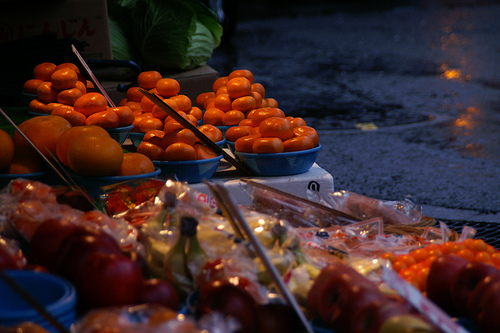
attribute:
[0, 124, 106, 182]
oranges — piled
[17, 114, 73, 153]
tomato — here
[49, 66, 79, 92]
tomato — here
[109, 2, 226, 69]
dark leaves — green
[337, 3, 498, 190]
reflection — concrete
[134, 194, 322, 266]
yellow bananas — bunched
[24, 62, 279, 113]
stacks of oranges — furthest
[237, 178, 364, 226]
stick — brown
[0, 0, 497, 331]
lights — on